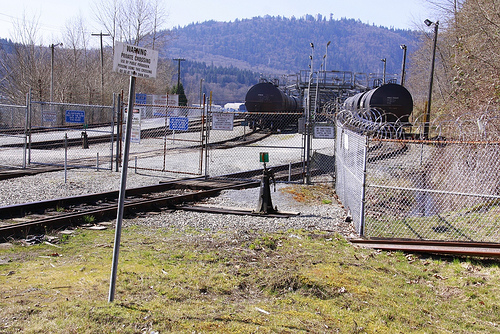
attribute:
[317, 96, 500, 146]
wire — barbed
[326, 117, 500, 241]
fence — rusted, aluminum, metal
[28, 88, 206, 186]
gate — chain link, security, chain linked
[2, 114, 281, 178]
tracks — brown, old, train, railroad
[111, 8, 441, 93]
mounts — covered, background, distance, trees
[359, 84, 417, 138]
cars — cylinder, black, parked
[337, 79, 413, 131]
train — black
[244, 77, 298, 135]
cars — cylinder, black, parked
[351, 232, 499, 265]
plank — wood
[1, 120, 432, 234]
ground — gravel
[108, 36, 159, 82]
sign — warning, white, blue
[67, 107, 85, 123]
sign — blue, white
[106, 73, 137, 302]
pole — thin, metal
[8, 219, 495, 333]
grass — green, thin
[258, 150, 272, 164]
flag — green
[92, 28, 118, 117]
poles — telephone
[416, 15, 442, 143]
lamp — tall, metal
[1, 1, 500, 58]
sky — clear, blue